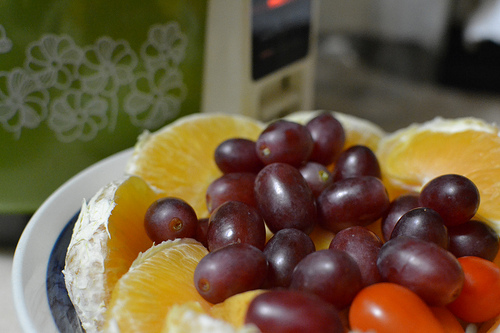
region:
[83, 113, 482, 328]
orange slices on plate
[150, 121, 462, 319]
grapes on top of orange slices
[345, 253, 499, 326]
tiny red tomatoes beside grapes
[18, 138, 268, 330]
white plate with blue stripe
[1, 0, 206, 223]
green dishware with white flower print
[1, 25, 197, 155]
white flowers on green dish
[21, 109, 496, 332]
plate full of fruit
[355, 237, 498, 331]
grape in between two tomatoes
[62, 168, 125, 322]
white on orange slice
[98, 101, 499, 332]
group of grapes, tomatoes, and orange slices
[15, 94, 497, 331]
A plate of fruit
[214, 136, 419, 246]
A group of red grapes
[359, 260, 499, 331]
Red cherry tomatoes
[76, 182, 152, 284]
An orange slice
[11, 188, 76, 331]
A white plate with blue design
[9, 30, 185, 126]
White design on wall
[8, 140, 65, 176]
Green wall in the background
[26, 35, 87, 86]
A floral design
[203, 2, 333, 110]
An appliance in background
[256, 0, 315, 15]
A red light on the appliance in background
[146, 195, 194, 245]
a small red grape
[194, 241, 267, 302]
a small red grape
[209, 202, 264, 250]
a small red grape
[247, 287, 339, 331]
a small red grape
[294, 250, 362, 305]
a small red grape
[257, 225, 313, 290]
a small red grape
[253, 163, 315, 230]
a small red grape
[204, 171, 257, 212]
a small red grape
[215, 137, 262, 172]
a small red grape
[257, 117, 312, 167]
a small red grape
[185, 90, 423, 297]
purple grapes on plate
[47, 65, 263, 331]
sliced oranges are on plate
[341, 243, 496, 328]
small red tomatoes on plate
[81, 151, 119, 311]
white rind of orange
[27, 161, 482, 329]
fruits are on blue and white plate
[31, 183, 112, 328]
blue ring on white plate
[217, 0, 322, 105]
small monitor is behind plate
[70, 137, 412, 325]
assorted fruit on round plate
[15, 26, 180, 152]
white flowers on green wall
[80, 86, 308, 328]
oranges have been peeled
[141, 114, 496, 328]
stemless purple grapes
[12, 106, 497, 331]
fresh fruit on a bowl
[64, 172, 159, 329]
slice of orange on a bowl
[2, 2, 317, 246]
blurry objects in the background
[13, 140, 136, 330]
white bowl with blue stripe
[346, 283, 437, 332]
cherry tomoato next to grapes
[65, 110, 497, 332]
orange slices on a bowl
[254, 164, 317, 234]
large purple grape on a fruit platter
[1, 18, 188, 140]
white flower pattern on a green object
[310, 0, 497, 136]
area of the room is blurry